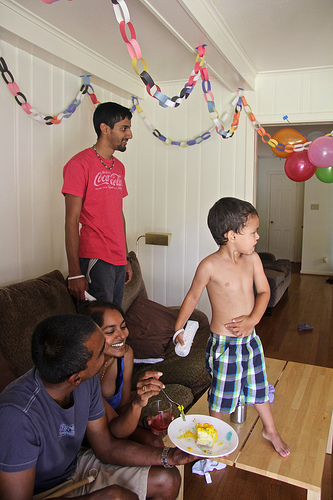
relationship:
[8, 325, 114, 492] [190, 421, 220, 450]
man eating cake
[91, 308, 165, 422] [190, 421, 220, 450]
woman eating cake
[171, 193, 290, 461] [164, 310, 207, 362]
boy holding controller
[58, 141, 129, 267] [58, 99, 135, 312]
shirt on man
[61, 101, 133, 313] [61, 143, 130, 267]
man wears shirt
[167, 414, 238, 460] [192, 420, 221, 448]
plate has cake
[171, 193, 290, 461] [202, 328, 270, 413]
boy wears shorts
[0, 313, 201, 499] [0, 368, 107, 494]
man wears shirt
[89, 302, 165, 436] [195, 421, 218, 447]
woman eating cake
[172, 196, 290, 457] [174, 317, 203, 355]
boy holding controller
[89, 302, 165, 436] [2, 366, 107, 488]
woman wearing shirt